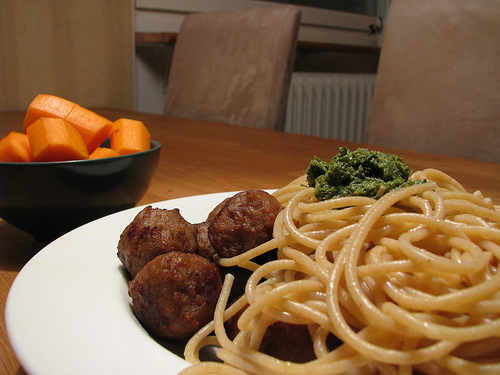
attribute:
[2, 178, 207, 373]
plate — white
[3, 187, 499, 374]
plate — white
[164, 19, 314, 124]
chair — plush, tan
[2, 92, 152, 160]
food — orange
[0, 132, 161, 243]
bowl — black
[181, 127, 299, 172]
table — brown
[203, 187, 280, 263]
ball — brown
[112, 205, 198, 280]
ball — brown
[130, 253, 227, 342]
ball — brown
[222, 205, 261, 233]
meat — brown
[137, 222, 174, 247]
meat — brown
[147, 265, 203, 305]
meat — brown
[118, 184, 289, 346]
balls — brown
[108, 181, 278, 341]
meatballs — brown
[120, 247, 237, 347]
meatballs — brown, round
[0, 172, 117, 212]
bowl — black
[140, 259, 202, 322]
meat — brown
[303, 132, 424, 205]
paste — thick, green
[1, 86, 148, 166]
carrots — sliced